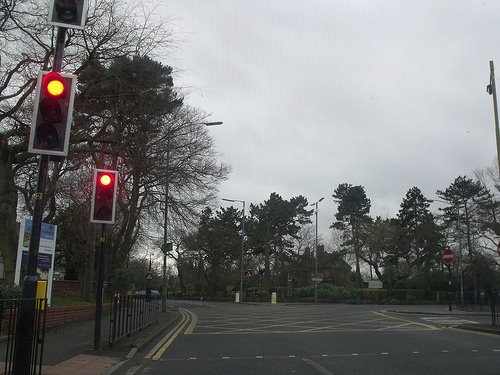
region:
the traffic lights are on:
[19, 63, 254, 259]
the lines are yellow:
[174, 298, 229, 372]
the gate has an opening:
[22, 288, 153, 356]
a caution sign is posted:
[434, 228, 497, 335]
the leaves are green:
[171, 235, 377, 336]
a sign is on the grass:
[10, 210, 161, 355]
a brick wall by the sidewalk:
[47, 292, 109, 343]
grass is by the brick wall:
[51, 278, 116, 348]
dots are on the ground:
[155, 348, 465, 358]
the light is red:
[70, 155, 180, 206]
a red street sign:
[438, 243, 455, 308]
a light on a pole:
[163, 116, 227, 261]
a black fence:
[102, 285, 169, 337]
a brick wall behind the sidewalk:
[3, 304, 119, 326]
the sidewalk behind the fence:
[26, 303, 158, 347]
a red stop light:
[23, 62, 78, 154]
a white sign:
[21, 219, 61, 306]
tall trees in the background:
[195, 185, 490, 306]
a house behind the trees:
[262, 247, 345, 288]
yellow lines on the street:
[182, 297, 439, 339]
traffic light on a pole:
[87, 158, 122, 308]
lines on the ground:
[151, 285, 461, 357]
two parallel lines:
[139, 322, 186, 361]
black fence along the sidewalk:
[103, 285, 182, 346]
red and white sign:
[437, 245, 457, 267]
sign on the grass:
[17, 210, 60, 304]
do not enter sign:
[438, 245, 458, 263]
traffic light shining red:
[26, 60, 82, 170]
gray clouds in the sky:
[8, 0, 494, 251]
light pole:
[219, 196, 256, 298]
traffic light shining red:
[89, 167, 124, 234]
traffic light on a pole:
[23, 69, 90, 217]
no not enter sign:
[435, 247, 458, 264]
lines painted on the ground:
[152, 294, 459, 364]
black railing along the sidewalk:
[99, 284, 176, 345]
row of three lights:
[26, 70, 79, 155]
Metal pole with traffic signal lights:
[0, 64, 135, 361]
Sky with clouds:
[297, 20, 430, 149]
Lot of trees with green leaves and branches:
[126, 42, 469, 239]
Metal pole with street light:
[307, 195, 329, 299]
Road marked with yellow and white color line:
[171, 292, 473, 370]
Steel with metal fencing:
[108, 293, 170, 335]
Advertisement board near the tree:
[21, 213, 62, 318]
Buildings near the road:
[302, 240, 350, 288]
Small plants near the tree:
[303, 276, 427, 300]